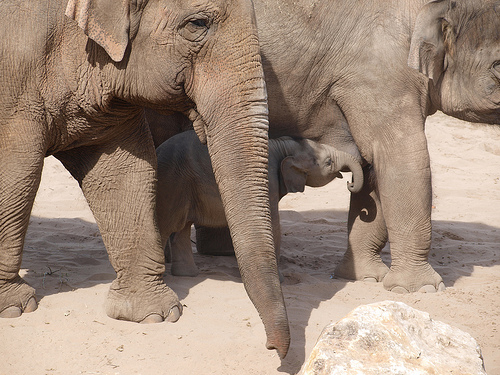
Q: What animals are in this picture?
A: Elephants.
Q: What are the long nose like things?
A: Trunks.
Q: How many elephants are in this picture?
A: Three.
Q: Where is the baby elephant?
A: Between the other elephants.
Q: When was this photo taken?
A: During the daytime.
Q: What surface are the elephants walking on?
A: Sand.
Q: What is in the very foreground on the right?
A: A rock.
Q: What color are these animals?
A: Gray.